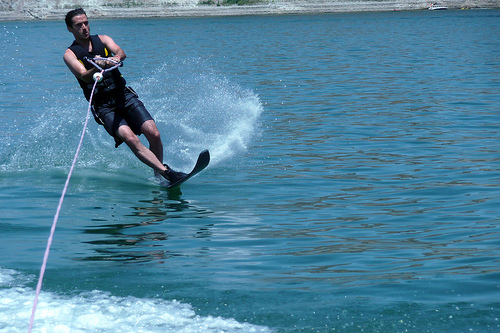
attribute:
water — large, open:
[0, 10, 497, 332]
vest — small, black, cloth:
[56, 38, 131, 109]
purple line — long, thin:
[19, 75, 101, 331]